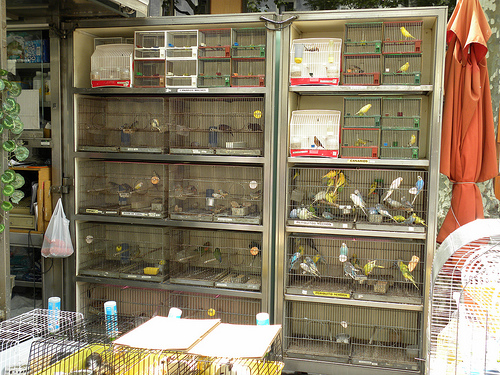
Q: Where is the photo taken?
A: Pet shop.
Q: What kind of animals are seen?
A: Birds.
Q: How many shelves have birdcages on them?
A: Ten.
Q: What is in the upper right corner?
A: Umbrella.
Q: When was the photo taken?
A: Daytime.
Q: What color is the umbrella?
A: Orange.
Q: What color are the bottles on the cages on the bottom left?
A: Blue.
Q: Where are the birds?
A: Cages.